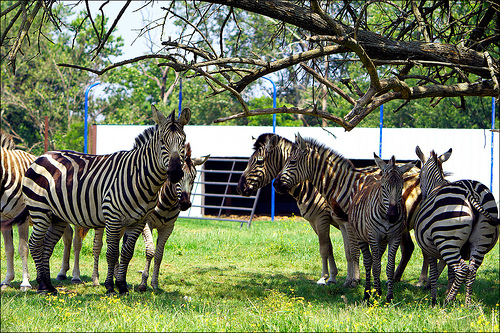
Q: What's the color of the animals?
A: Black and white.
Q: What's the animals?
A: Zebras.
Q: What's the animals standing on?
A: Grass.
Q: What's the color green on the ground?
A: Grass.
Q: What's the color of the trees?
A: Green.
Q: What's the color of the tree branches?
A: Brown.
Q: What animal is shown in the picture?
A: Zebras.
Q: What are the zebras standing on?
A: Grass.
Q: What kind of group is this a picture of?
A: A group of zebras.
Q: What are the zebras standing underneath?
A: A tree.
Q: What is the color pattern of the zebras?
A: The zebras are black and white.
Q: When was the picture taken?
A: On a nice, sunny day.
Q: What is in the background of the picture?
A: A white building.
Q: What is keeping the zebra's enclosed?
A: A silver gate.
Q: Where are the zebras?
A: Green field.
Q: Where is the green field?
A: Zoo.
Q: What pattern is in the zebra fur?
A: Stripes.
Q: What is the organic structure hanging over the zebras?
A: Tree branches.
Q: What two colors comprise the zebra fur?
A: Black and white.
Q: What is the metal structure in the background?
A: Metal fencing.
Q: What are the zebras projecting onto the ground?
A: Shadows.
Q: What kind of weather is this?
A: Sunny.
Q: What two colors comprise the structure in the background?
A: Blue and white.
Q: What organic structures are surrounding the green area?
A: Trees and foliage.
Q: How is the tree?
A: Bare.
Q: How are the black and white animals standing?
A: Together.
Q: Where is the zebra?
A: Near building.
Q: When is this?
A: Daytime.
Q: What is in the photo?
A: Zebras.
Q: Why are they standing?
A: Motionless.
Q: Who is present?
A: No one.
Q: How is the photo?
A: Clear.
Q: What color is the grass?
A: Green.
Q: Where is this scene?
A: At the zoo.